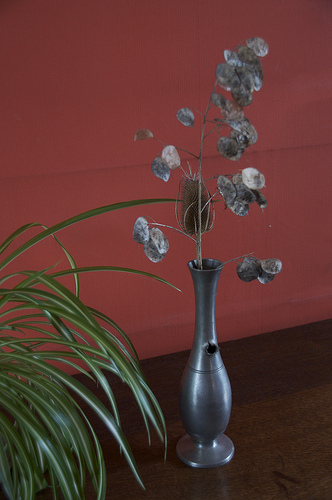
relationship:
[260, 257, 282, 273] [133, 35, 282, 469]
leaf of plant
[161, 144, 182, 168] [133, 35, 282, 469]
leaf of plant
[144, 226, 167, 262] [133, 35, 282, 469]
leaf of plant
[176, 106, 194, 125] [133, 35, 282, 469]
leaf of plant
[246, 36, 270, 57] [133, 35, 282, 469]
leaf of plant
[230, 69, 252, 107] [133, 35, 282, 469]
leaf of plant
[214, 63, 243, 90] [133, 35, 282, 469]
leaf of plant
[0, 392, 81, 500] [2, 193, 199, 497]
leaves on a plant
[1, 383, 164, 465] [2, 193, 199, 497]
leaves on a plant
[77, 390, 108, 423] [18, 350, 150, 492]
stripe on leaf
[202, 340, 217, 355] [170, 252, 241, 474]
hole in vase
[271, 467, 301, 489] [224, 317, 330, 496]
marks on table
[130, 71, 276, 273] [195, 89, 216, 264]
plant has stem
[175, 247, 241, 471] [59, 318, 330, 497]
vase on table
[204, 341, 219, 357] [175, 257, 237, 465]
hole in vase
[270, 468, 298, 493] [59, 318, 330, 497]
dark brown on table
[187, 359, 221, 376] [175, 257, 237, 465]
line on vase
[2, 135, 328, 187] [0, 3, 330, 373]
line in wall